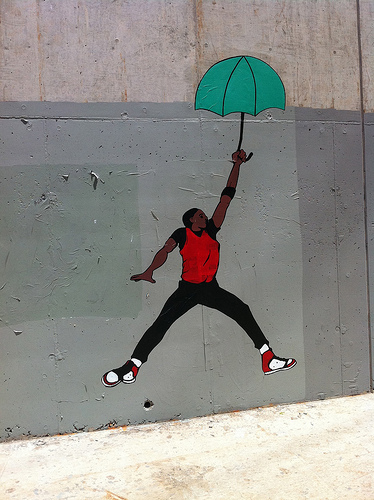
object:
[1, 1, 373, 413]
wall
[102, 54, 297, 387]
painting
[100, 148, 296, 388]
man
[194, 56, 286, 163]
umbrella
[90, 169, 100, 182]
nail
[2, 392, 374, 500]
sidewalk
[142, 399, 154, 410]
hole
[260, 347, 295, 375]
sneaker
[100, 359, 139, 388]
sneaker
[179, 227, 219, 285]
jersey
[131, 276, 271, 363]
pants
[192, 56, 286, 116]
canopy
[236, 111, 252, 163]
shaft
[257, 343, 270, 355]
sock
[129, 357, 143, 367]
sock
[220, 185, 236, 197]
band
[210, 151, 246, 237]
arm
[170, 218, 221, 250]
tee shirt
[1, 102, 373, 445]
paint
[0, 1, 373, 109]
top